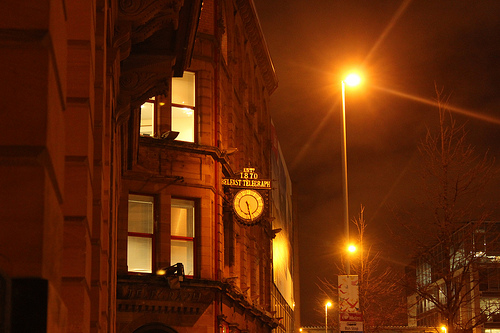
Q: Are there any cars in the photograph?
A: No, there are no cars.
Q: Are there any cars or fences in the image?
A: No, there are no cars or fences.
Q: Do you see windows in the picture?
A: Yes, there is a window.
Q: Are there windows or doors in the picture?
A: Yes, there is a window.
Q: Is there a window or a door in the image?
A: Yes, there is a window.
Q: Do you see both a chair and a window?
A: No, there is a window but no chairs.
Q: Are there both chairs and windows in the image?
A: No, there is a window but no chairs.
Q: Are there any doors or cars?
A: No, there are no cars or doors.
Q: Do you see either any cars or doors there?
A: No, there are no cars or doors.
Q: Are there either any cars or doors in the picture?
A: No, there are no cars or doors.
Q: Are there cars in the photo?
A: No, there are no cars.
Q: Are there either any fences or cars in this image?
A: No, there are no cars or fences.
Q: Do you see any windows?
A: Yes, there is a window.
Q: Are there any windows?
A: Yes, there is a window.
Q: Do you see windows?
A: Yes, there is a window.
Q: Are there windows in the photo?
A: Yes, there is a window.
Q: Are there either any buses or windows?
A: Yes, there is a window.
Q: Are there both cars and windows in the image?
A: No, there is a window but no cars.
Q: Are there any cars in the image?
A: No, there are no cars.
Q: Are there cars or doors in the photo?
A: No, there are no cars or doors.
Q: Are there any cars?
A: No, there are no cars.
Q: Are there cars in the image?
A: No, there are no cars.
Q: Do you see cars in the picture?
A: No, there are no cars.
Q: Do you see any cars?
A: No, there are no cars.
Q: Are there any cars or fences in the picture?
A: No, there are no cars or fences.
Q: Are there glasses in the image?
A: No, there are no glasses.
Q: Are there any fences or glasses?
A: No, there are no glasses or fences.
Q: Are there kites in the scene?
A: No, there are no kites.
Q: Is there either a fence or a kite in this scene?
A: No, there are no kites or fences.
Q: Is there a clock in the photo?
A: Yes, there is a clock.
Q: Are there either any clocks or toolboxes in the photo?
A: Yes, there is a clock.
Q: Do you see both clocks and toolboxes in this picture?
A: No, there is a clock but no toolboxes.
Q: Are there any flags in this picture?
A: No, there are no flags.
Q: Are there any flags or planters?
A: No, there are no flags or planters.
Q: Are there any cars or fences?
A: No, there are no cars or fences.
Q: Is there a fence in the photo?
A: No, there are no fences.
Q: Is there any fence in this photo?
A: No, there are no fences.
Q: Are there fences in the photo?
A: No, there are no fences.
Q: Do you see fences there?
A: No, there are no fences.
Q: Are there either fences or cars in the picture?
A: No, there are no fences or cars.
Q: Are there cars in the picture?
A: No, there are no cars.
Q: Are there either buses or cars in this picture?
A: No, there are no cars or buses.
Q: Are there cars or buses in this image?
A: No, there are no cars or buses.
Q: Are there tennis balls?
A: No, there are no tennis balls.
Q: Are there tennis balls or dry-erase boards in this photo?
A: No, there are no tennis balls or dry-erase boards.